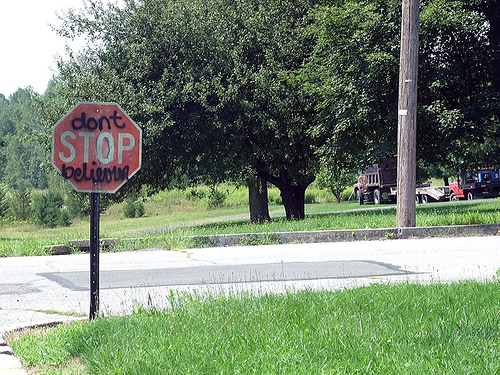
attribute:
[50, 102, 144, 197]
sign — marked, red, white, octagon, metal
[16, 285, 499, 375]
grass — healthy, thick, green, high, lush, overgrown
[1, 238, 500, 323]
road — paved, sunny, grey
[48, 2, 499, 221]
tree — healthy, large, big, green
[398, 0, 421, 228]
pole — thick wood, large, wood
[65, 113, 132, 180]
graffiti — black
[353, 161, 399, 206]
truck — parked, large, red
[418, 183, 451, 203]
trailer — empty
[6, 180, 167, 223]
evergreens — young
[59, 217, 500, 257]
curb — cement